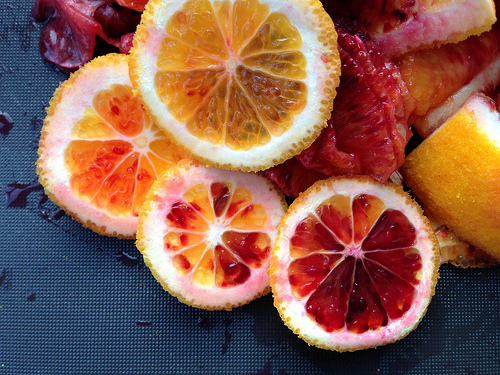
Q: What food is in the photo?
A: Oranges.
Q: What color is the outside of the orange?
A: Orange.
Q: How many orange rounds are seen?
A: Four.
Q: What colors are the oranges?
A: Orange, red.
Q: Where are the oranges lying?
A: Table.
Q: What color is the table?
A: Blue.